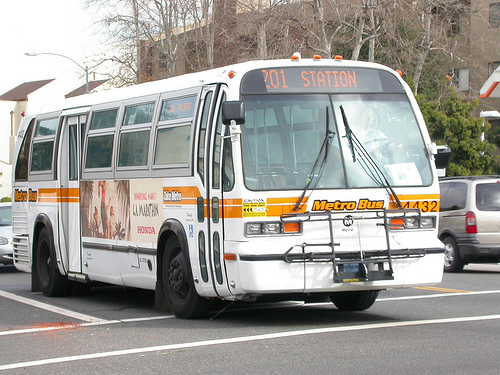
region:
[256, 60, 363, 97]
Orange LED sign reading 201 Station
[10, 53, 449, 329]
A white and orange bus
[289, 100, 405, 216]
Two black windshield wipers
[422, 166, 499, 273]
A gray vehicle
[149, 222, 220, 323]
A large black tire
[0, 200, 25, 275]
A gray car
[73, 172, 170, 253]
An advertisement on the side of the bus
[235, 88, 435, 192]
The glass windshield of the bus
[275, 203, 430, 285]
A bike rack on the front of the bus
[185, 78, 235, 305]
A door on the side of the bus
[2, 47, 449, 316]
a bus on the street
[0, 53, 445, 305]
the bus frame is white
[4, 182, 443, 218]
an orange stripe around the bus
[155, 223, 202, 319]
the bus wheel is black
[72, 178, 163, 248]
an advertisement on the side of the bus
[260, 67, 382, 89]
the destination shown on the front of the bus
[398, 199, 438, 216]
the bus number is 4432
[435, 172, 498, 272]
a van is beside the bus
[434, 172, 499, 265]
the van is grey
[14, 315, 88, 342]
a red spill on the street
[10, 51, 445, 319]
white bus is driving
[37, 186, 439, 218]
orange lines on bus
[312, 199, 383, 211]
orange writing on front of bus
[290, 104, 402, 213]
black wipers on front of bus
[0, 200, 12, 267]
silver car behind bus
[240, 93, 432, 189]
large windshield on front of bus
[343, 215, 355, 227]
small black logo on front of bus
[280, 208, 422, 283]
black bike rack on front of bus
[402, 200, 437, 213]
black numbering on front of bus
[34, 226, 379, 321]
black tires on bus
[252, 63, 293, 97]
The number 201 on bus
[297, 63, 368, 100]
Word station on bus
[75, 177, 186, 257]
Advertisement on side of bus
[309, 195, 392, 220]
Words "Metro Bus" on front of bus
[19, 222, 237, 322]
Black wheels on bus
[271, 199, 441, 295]
Silver bike rack on bus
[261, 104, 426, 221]
Black windshield wipers on bus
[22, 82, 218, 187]
Side windows on bus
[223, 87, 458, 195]
Front windshield of bus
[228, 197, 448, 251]
Front headlights of bus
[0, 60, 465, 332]
The bus is primarily white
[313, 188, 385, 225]
Metro Bus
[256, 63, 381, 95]
Bus heading to 201 Station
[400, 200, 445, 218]
Bus #4432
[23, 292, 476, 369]
White lines on the road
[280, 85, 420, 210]
Two windshield wipers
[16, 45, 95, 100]
Light pole behind the bus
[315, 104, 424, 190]
Bus driver in his seat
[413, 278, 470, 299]
Yellow line in the road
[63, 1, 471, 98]
trees with no leaves